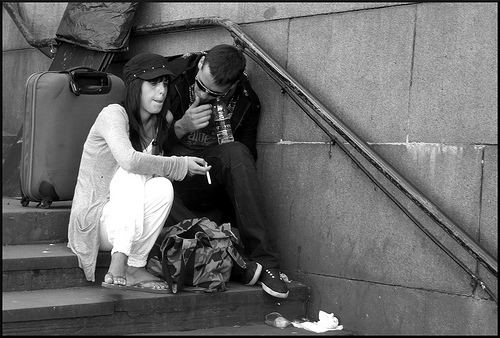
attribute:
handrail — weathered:
[1, 4, 498, 280]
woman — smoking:
[67, 56, 212, 295]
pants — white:
[99, 166, 173, 267]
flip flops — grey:
[101, 273, 176, 295]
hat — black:
[122, 53, 178, 83]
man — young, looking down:
[169, 46, 290, 299]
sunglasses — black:
[195, 67, 230, 99]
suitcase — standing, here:
[18, 68, 126, 208]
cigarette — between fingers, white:
[204, 164, 211, 183]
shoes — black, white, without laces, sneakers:
[235, 258, 285, 298]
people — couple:
[67, 43, 288, 301]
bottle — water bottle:
[215, 98, 234, 144]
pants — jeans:
[165, 142, 283, 271]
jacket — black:
[164, 54, 259, 161]